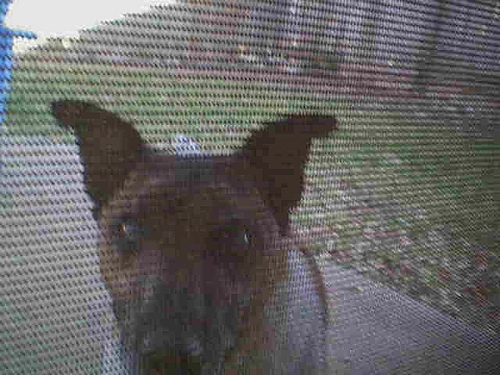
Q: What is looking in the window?
A: A dog.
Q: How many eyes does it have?
A: 2.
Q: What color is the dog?
A: Brown and white.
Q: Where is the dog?
A: Outside the house.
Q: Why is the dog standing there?
A: He wants in.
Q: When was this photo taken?
A: Daytime.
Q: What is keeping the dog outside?
A: Screen.